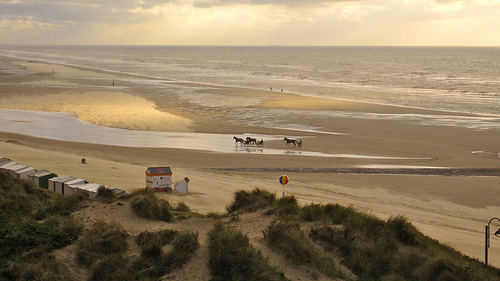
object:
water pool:
[2, 108, 432, 159]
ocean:
[0, 44, 497, 131]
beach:
[0, 61, 497, 281]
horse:
[283, 137, 298, 147]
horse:
[248, 137, 256, 144]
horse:
[233, 135, 244, 144]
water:
[0, 45, 499, 115]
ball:
[278, 175, 289, 186]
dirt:
[231, 153, 345, 177]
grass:
[0, 171, 497, 281]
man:
[258, 141, 262, 147]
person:
[269, 85, 272, 91]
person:
[280, 88, 284, 92]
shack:
[145, 166, 173, 192]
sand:
[59, 158, 138, 181]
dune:
[230, 209, 270, 244]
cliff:
[53, 196, 500, 281]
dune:
[82, 205, 133, 224]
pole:
[483, 226, 490, 266]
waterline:
[3, 56, 500, 117]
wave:
[430, 70, 481, 86]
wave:
[270, 62, 302, 71]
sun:
[60, 91, 171, 126]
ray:
[264, 95, 360, 110]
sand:
[213, 155, 285, 170]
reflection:
[234, 147, 304, 154]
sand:
[444, 208, 475, 243]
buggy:
[296, 139, 302, 148]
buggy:
[257, 139, 264, 147]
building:
[76, 182, 114, 199]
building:
[6, 163, 37, 182]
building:
[27, 168, 59, 190]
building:
[0, 158, 12, 167]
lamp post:
[484, 225, 491, 266]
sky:
[0, 0, 500, 47]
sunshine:
[259, 95, 359, 107]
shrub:
[273, 193, 301, 215]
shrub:
[231, 186, 275, 208]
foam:
[430, 72, 500, 84]